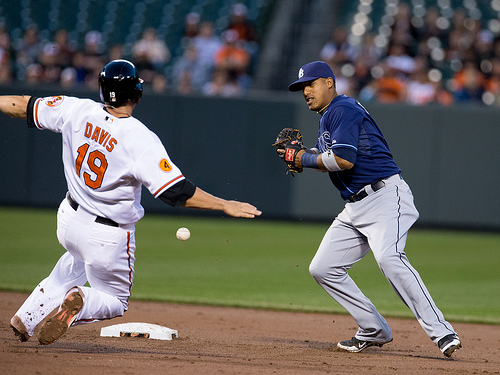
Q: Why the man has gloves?
A: He's a player.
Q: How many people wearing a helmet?
A: One.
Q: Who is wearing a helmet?
A: A man.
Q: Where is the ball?
A: Floating.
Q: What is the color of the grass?
A: Green.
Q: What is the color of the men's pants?
A: White.